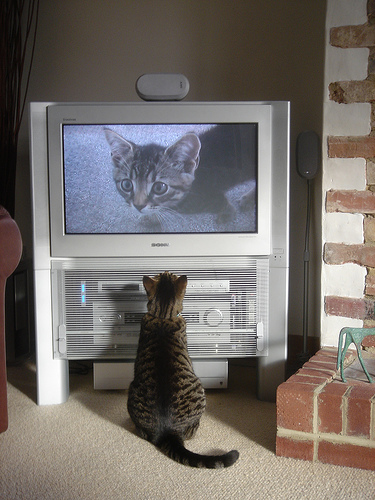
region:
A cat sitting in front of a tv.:
[125, 269, 239, 468]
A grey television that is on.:
[43, 101, 289, 256]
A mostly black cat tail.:
[158, 434, 241, 467]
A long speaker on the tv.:
[135, 72, 189, 100]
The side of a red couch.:
[0, 203, 25, 430]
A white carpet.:
[1, 364, 372, 498]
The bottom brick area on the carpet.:
[275, 344, 373, 470]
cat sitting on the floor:
[125, 269, 245, 470]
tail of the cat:
[160, 434, 246, 471]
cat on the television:
[101, 125, 210, 221]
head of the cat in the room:
[140, 266, 189, 317]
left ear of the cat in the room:
[139, 272, 155, 296]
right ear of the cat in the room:
[175, 273, 190, 296]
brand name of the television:
[148, 241, 172, 249]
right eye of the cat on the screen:
[119, 175, 138, 196]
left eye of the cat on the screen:
[151, 180, 170, 195]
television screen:
[56, 120, 261, 240]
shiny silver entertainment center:
[31, 99, 289, 404]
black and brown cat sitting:
[123, 268, 240, 469]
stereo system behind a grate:
[86, 275, 234, 391]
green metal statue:
[333, 322, 373, 387]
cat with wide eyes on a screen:
[62, 120, 258, 234]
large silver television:
[45, 101, 274, 257]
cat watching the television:
[46, 102, 276, 470]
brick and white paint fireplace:
[273, 32, 373, 472]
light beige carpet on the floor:
[0, 354, 373, 498]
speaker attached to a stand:
[294, 127, 322, 362]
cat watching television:
[115, 274, 241, 465]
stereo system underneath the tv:
[75, 277, 239, 391]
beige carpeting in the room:
[7, 356, 373, 498]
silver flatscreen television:
[46, 101, 274, 260]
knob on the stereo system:
[204, 309, 228, 330]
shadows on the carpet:
[10, 349, 277, 455]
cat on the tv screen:
[62, 124, 256, 232]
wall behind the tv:
[14, 4, 311, 342]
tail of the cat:
[148, 439, 241, 468]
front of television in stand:
[31, 100, 288, 405]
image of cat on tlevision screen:
[65, 121, 258, 234]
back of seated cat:
[125, 271, 238, 468]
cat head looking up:
[143, 270, 187, 313]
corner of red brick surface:
[276, 346, 372, 469]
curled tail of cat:
[159, 435, 239, 468]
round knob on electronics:
[204, 309, 224, 327]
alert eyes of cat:
[121, 178, 167, 196]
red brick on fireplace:
[347, 384, 371, 441]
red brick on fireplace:
[316, 382, 344, 437]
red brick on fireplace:
[274, 378, 316, 434]